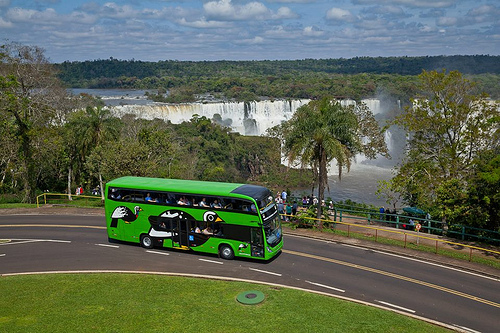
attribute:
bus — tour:
[59, 134, 319, 294]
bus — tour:
[80, 160, 307, 272]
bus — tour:
[116, 157, 282, 267]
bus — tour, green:
[101, 169, 286, 264]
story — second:
[105, 182, 255, 216]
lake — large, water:
[133, 58, 458, 190]